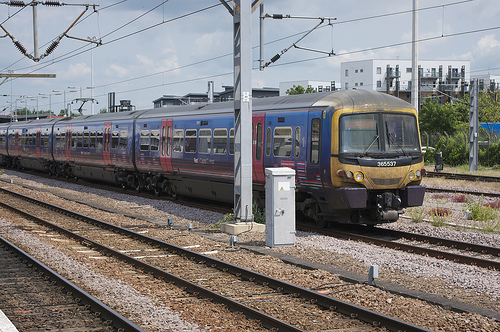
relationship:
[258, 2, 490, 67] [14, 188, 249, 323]
power lines above tracks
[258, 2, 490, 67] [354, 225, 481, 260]
power lines above tracks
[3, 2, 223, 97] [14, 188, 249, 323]
power lines above tracks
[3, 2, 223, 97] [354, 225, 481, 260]
power lines above tracks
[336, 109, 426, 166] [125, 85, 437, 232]
window of train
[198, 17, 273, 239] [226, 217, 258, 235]
pole of pavement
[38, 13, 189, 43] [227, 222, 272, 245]
lines on pavement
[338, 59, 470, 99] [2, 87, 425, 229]
building behind train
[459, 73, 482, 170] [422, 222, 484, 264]
pole on tracks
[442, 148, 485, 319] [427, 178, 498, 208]
set of tracks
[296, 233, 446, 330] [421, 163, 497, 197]
set of tracks